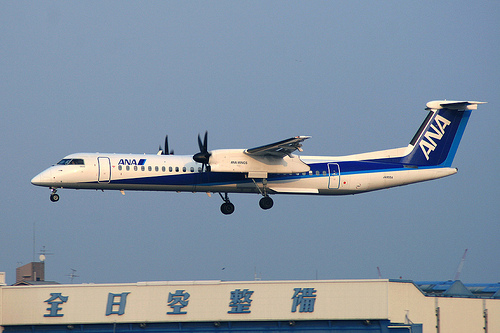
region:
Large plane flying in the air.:
[27, 77, 475, 234]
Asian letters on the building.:
[39, 279, 326, 329]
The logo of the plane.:
[420, 94, 448, 169]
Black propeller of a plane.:
[189, 133, 217, 179]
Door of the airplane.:
[326, 161, 344, 193]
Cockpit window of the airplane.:
[52, 153, 87, 170]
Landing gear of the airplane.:
[213, 188, 290, 221]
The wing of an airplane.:
[232, 120, 332, 167]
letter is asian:
[40, 289, 69, 320]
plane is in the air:
[29, 96, 489, 208]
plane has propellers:
[24, 95, 491, 214]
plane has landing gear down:
[28, 94, 489, 209]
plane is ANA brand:
[31, 95, 491, 217]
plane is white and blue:
[25, 95, 491, 205]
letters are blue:
[34, 286, 326, 325]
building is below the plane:
[3, 283, 486, 320]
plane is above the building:
[36, 93, 480, 213]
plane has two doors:
[27, 97, 492, 204]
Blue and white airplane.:
[30, 100, 485, 210]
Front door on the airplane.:
[99, 156, 110, 182]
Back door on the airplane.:
[328, 162, 340, 188]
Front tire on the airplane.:
[50, 193, 60, 200]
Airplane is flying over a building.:
[32, 100, 487, 211]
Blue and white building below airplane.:
[1, 278, 498, 332]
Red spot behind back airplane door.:
[343, 180, 345, 182]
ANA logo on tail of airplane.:
[419, 113, 450, 158]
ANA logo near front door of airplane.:
[119, 158, 137, 165]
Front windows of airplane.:
[56, 158, 83, 165]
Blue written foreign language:
[37, 283, 330, 322]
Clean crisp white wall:
[448, 305, 468, 330]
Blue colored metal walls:
[338, 320, 367, 329]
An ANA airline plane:
[411, 89, 486, 182]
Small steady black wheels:
[218, 197, 240, 222]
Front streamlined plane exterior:
[27, 146, 104, 193]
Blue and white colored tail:
[411, 83, 490, 184]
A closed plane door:
[326, 159, 346, 194]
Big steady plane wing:
[242, 131, 316, 161]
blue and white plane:
[11, 98, 483, 182]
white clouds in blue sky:
[317, 35, 362, 96]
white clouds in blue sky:
[212, 39, 252, 101]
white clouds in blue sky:
[292, 33, 316, 68]